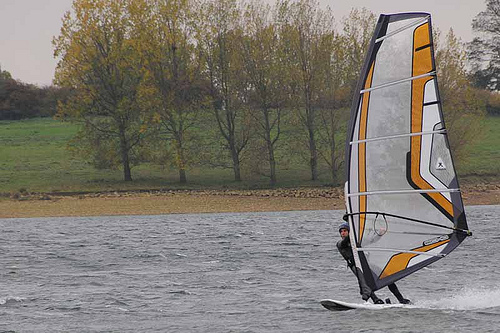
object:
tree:
[51, 1, 168, 184]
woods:
[52, 2, 491, 181]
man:
[323, 223, 418, 314]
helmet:
[338, 222, 350, 231]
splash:
[425, 290, 499, 310]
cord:
[342, 211, 472, 237]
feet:
[374, 299, 384, 304]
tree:
[3, 87, 51, 117]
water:
[68, 205, 371, 322]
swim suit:
[336, 239, 404, 303]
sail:
[343, 11, 472, 301]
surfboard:
[319, 299, 420, 311]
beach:
[2, 189, 342, 213]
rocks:
[105, 190, 345, 197]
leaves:
[63, 2, 154, 108]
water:
[14, 233, 304, 326]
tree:
[277, 0, 338, 179]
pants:
[349, 261, 412, 304]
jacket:
[336, 237, 355, 268]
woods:
[3, 1, 499, 201]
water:
[2, 205, 484, 331]